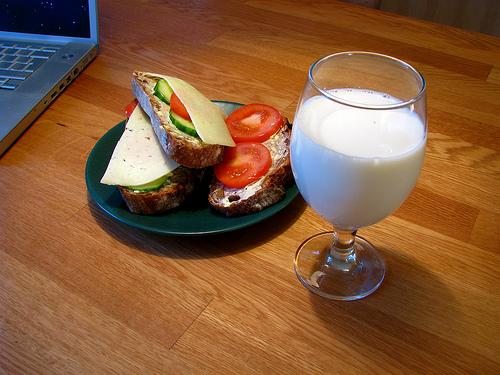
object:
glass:
[289, 51, 427, 302]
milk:
[289, 88, 427, 228]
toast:
[208, 103, 293, 218]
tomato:
[214, 103, 283, 189]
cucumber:
[152, 78, 201, 139]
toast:
[132, 70, 237, 168]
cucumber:
[121, 171, 173, 193]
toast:
[100, 102, 205, 216]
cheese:
[144, 72, 237, 147]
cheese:
[100, 102, 181, 186]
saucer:
[84, 100, 300, 235]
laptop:
[0, 0, 100, 158]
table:
[0, 0, 499, 375]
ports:
[43, 67, 80, 105]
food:
[100, 70, 293, 219]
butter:
[211, 126, 289, 208]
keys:
[0, 43, 60, 90]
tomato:
[170, 91, 193, 122]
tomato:
[124, 100, 140, 118]